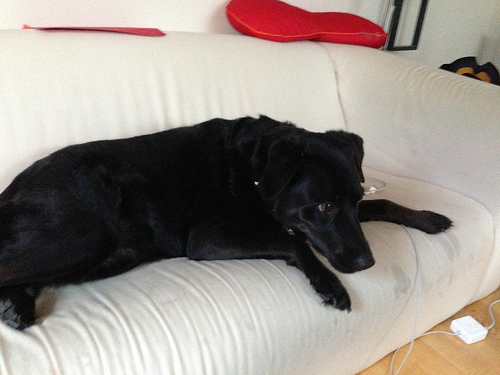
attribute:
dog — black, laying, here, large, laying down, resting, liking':
[3, 112, 458, 331]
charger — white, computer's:
[365, 175, 498, 375]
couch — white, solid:
[2, 23, 500, 372]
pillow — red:
[225, 2, 393, 47]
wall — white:
[5, 1, 500, 90]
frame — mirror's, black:
[386, 0, 431, 55]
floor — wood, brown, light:
[360, 287, 500, 373]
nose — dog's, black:
[357, 255, 374, 271]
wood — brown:
[360, 288, 500, 375]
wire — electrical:
[366, 173, 499, 367]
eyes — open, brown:
[311, 191, 364, 213]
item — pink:
[23, 23, 168, 37]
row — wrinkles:
[42, 60, 257, 147]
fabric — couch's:
[0, 35, 499, 375]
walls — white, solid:
[7, 1, 499, 86]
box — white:
[453, 314, 488, 348]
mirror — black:
[383, 1, 437, 57]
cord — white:
[367, 174, 498, 373]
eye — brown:
[316, 200, 333, 214]